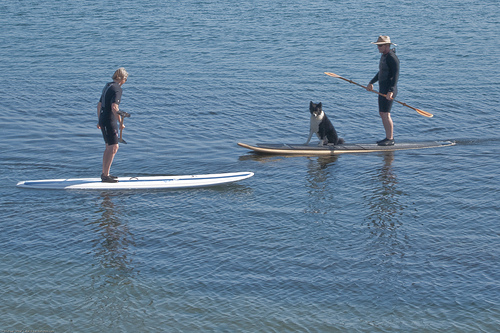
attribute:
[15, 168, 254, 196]
surfboard — white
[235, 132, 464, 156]
surfboard — brown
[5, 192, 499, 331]
water — blue, calm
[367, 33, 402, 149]
man — holding, boarding, wearing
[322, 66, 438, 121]
paddle — black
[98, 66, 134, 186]
man — standing